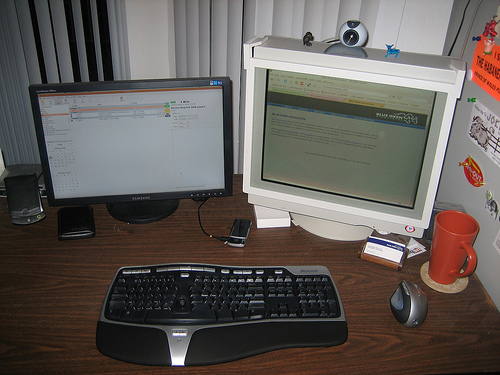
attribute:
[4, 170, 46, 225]
speaker — desktop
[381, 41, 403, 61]
horse — small, plastic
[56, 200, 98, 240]
wallet — black, leathery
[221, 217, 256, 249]
phone — plugged in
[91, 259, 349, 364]
keyboard — silver, black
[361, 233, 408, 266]
business cards — stacked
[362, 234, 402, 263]
business card — white, blue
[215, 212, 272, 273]
cellphone — cell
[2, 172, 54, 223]
speaker — computer speaker, silver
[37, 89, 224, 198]
screen — white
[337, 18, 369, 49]
web cam — small, round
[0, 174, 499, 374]
desk — wooden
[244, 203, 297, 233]
pad — small, paper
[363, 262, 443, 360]
mouse — wireless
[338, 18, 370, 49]
webcam — is circular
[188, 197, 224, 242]
cord — charging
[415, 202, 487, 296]
cup — orange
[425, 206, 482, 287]
mug — red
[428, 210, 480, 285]
coffee mug — orange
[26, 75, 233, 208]
monitor — computer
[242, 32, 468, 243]
monitor — white, computer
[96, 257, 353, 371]
keyboard — black, silver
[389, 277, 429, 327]
mouse — silver, black, wireless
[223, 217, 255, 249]
cellphone — charging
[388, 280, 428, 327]
wireless mouse — silver, black